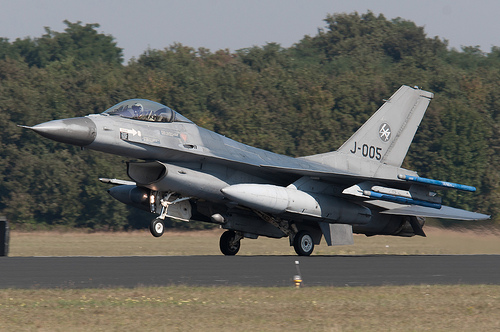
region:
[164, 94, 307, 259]
this is a plane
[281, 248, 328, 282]
this is a wheel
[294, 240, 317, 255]
the wheel is white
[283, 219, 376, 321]
the wheel is metal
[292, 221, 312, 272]
this is a tire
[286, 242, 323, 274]
the tire is black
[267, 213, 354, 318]
the tire is made of rubber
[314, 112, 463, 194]
this is a tail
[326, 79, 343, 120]
the tree is old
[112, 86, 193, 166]
this is a window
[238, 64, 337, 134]
the green bush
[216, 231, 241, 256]
wheel on the jet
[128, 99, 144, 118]
pilot of the jet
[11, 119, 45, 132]
the nose of the jet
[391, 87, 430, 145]
the tail of the jet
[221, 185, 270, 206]
a missle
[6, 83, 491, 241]
the jet is flying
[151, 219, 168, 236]
the front wheel of the jet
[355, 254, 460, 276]
the roadway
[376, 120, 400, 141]
logo on the tail of the jet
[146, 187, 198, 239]
landing gear below jet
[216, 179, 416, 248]
cockpit of jet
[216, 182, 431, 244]
missle beneath jet wing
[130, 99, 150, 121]
pilot in cockpit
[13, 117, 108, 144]
nose of the aircraft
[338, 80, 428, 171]
grey metal tail of the aircraft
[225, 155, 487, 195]
wing of the aircraft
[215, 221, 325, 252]
rear landing gear of aircraft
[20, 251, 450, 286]
runway of airfield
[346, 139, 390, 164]
J-005 on aircraft tail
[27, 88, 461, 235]
jet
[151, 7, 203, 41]
white clouds in blue sky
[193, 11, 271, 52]
white clouds in blue sky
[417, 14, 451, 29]
white clouds in blue sky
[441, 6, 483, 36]
white clouds in blue sky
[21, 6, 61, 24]
white clouds in blue sky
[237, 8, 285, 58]
white clouds in blue sky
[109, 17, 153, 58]
white clouds in blue sky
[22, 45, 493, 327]
a small and gray jet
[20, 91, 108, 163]
the nose of a jet plane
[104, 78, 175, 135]
the cockpit of a jet plane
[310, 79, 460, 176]
the tail of a jet plane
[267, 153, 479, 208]
the wing of a jet plane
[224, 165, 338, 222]
the turbine of a jet plane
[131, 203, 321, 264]
the wheels of a jet plane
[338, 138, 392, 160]
the number of a jet plane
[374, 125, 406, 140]
the logo of a jet plane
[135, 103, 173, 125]
the chair of a jet plane